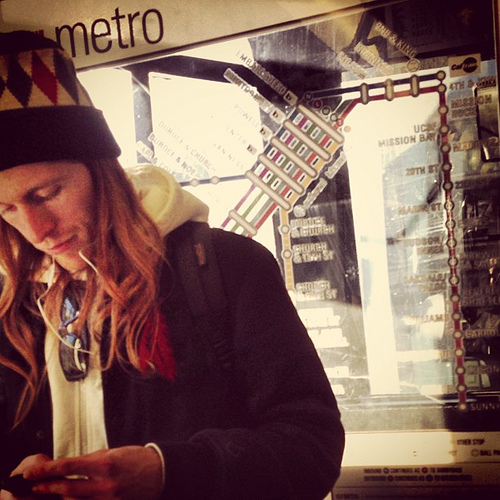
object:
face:
[0, 158, 95, 274]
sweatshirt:
[35, 261, 118, 455]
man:
[0, 21, 353, 486]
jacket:
[4, 158, 346, 500]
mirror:
[121, 66, 481, 406]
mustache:
[48, 227, 75, 239]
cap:
[0, 29, 123, 167]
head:
[1, 67, 115, 271]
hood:
[126, 164, 213, 233]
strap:
[171, 219, 232, 343]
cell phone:
[4, 471, 62, 496]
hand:
[16, 443, 161, 492]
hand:
[7, 450, 55, 493]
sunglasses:
[55, 275, 95, 382]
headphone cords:
[36, 271, 93, 357]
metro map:
[336, 51, 500, 413]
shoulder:
[159, 218, 297, 358]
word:
[52, 2, 164, 60]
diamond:
[27, 46, 63, 103]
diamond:
[4, 52, 33, 108]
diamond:
[50, 42, 80, 98]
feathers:
[150, 311, 178, 384]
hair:
[80, 155, 179, 370]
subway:
[1, 5, 500, 488]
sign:
[44, 1, 164, 62]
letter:
[90, 17, 113, 55]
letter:
[54, 22, 90, 59]